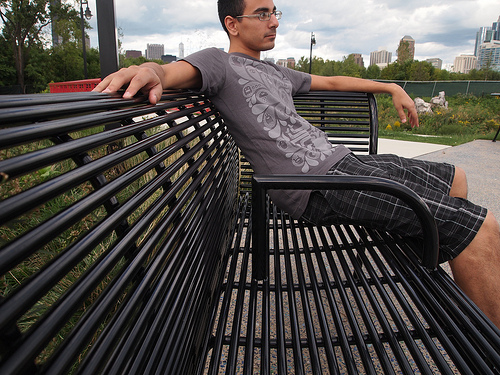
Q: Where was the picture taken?
A: In a park.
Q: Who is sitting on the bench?
A: A man.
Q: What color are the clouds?
A: White.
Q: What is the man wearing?
A: Shorts and a T shirt.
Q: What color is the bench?
A: Black.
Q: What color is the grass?
A: Green.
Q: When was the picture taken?
A: During the day.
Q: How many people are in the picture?
A: One.